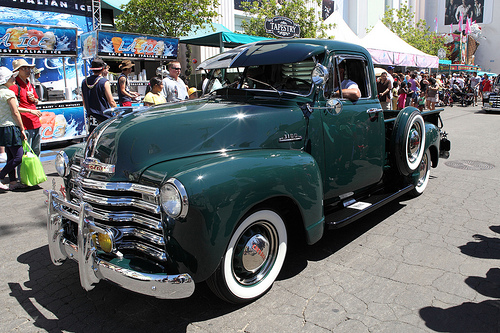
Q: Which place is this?
A: It is a road.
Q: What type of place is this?
A: It is a road.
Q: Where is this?
A: This is at the road.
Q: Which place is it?
A: It is a road.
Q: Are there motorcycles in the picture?
A: No, there are no motorcycles.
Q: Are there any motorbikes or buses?
A: No, there are no motorbikes or buses.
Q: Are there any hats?
A: Yes, there is a hat.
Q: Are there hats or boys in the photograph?
A: Yes, there is a hat.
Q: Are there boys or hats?
A: Yes, there is a hat.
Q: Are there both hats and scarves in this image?
A: No, there is a hat but no scarves.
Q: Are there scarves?
A: No, there are no scarves.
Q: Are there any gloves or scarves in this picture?
A: No, there are no scarves or gloves.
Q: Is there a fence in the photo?
A: No, there are no fences.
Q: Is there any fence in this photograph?
A: No, there are no fences.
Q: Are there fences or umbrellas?
A: No, there are no fences or umbrellas.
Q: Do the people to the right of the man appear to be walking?
A: Yes, the people are walking.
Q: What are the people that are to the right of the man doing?
A: The people are walking.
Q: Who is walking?
A: The people are walking.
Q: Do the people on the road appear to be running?
A: No, the people are walking.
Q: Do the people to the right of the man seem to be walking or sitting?
A: The people are walking.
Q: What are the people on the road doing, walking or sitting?
A: The people are walking.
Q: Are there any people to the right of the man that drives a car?
A: Yes, there are people to the right of the man.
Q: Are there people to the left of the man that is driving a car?
A: No, the people are to the right of the man.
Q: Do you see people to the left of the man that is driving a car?
A: No, the people are to the right of the man.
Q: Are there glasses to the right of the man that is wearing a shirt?
A: No, there are people to the right of the man.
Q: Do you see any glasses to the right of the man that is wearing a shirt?
A: No, there are people to the right of the man.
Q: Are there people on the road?
A: Yes, there are people on the road.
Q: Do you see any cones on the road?
A: No, there are people on the road.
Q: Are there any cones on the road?
A: No, there are people on the road.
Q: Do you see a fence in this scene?
A: No, there are no fences.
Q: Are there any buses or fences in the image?
A: No, there are no fences or buses.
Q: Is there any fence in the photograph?
A: No, there are no fences.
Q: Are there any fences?
A: No, there are no fences.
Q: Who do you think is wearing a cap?
A: The man is wearing a cap.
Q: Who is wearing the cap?
A: The man is wearing a cap.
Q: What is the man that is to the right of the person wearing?
A: The man is wearing a cap.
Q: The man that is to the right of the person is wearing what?
A: The man is wearing a cap.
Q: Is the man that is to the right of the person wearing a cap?
A: Yes, the man is wearing a cap.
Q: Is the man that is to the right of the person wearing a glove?
A: No, the man is wearing a cap.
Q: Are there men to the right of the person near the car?
A: Yes, there is a man to the right of the person.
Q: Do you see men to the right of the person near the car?
A: Yes, there is a man to the right of the person.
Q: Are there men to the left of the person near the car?
A: No, the man is to the right of the person.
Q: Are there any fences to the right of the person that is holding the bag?
A: No, there is a man to the right of the person.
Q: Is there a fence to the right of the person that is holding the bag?
A: No, there is a man to the right of the person.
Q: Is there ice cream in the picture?
A: Yes, there is ice cream.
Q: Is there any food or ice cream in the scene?
A: Yes, there is ice cream.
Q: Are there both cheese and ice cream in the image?
A: No, there is ice cream but no cheese.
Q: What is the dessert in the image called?
A: The dessert is ice cream.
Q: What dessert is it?
A: The dessert is ice cream.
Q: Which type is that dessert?
A: This is ice cream.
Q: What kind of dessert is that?
A: This is ice cream.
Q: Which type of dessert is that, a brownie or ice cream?
A: This is ice cream.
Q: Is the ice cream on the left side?
A: Yes, the ice cream is on the left of the image.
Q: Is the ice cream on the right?
A: No, the ice cream is on the left of the image.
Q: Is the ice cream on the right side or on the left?
A: The ice cream is on the left of the image.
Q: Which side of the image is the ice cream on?
A: The ice cream is on the left of the image.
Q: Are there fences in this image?
A: No, there are no fences.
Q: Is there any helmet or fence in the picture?
A: No, there are no fences or helmets.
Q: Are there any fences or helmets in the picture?
A: No, there are no fences or helmets.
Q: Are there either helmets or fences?
A: No, there are no fences or helmets.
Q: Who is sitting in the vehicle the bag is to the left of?
A: The man is sitting in the car.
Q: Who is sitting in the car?
A: The man is sitting in the car.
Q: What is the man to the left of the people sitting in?
A: The man is sitting in the car.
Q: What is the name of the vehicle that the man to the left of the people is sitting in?
A: The vehicle is a car.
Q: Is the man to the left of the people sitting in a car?
A: Yes, the man is sitting in a car.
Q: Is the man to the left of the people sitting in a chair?
A: No, the man is sitting in a car.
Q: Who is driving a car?
A: The man is driving a car.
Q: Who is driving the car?
A: The man is driving a car.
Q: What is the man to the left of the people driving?
A: The man is driving a car.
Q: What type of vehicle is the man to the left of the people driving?
A: The man is driving a car.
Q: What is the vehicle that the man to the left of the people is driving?
A: The vehicle is a car.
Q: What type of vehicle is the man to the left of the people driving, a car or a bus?
A: The man is driving a car.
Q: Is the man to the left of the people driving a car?
A: Yes, the man is driving a car.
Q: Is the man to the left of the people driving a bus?
A: No, the man is driving a car.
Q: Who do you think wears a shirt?
A: The man wears a shirt.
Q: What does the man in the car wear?
A: The man wears a shirt.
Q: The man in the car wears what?
A: The man wears a shirt.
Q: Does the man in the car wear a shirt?
A: Yes, the man wears a shirt.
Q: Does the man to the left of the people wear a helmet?
A: No, the man wears a shirt.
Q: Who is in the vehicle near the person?
A: The man is in the car.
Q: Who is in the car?
A: The man is in the car.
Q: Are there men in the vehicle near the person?
A: Yes, there is a man in the car.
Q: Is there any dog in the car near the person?
A: No, there is a man in the car.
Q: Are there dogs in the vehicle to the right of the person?
A: No, there is a man in the car.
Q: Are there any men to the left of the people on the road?
A: Yes, there is a man to the left of the people.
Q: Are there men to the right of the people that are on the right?
A: No, the man is to the left of the people.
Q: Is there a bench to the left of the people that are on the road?
A: No, there is a man to the left of the people.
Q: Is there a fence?
A: No, there are no fences.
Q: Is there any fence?
A: No, there are no fences.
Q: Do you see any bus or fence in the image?
A: No, there are no fences or buses.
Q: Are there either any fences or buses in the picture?
A: No, there are no fences or buses.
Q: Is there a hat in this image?
A: Yes, there is a hat.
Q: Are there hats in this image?
A: Yes, there is a hat.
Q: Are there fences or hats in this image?
A: Yes, there is a hat.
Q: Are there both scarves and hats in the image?
A: No, there is a hat but no scarves.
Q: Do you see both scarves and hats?
A: No, there is a hat but no scarves.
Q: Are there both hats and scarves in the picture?
A: No, there is a hat but no scarves.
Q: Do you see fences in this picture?
A: No, there are no fences.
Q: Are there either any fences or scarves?
A: No, there are no fences or scarves.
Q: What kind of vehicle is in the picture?
A: The vehicle is a car.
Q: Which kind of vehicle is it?
A: The vehicle is a car.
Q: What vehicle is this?
A: This is a car.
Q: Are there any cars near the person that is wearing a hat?
A: Yes, there is a car near the person.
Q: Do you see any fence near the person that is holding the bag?
A: No, there is a car near the person.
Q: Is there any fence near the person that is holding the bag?
A: No, there is a car near the person.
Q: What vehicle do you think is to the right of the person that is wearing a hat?
A: The vehicle is a car.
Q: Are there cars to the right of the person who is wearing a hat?
A: Yes, there is a car to the right of the person.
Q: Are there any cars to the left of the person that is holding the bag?
A: No, the car is to the right of the person.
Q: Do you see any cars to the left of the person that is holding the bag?
A: No, the car is to the right of the person.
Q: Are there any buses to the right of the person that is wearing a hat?
A: No, there is a car to the right of the person.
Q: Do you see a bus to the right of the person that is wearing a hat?
A: No, there is a car to the right of the person.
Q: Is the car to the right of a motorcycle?
A: No, the car is to the right of the person.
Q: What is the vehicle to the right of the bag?
A: The vehicle is a car.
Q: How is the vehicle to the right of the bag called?
A: The vehicle is a car.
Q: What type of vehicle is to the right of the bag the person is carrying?
A: The vehicle is a car.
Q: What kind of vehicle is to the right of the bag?
A: The vehicle is a car.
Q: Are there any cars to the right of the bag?
A: Yes, there is a car to the right of the bag.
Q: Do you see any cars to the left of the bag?
A: No, the car is to the right of the bag.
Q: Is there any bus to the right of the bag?
A: No, there is a car to the right of the bag.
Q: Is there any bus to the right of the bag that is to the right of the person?
A: No, there is a car to the right of the bag.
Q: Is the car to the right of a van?
A: No, the car is to the right of the bag.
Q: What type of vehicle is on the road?
A: The vehicle is a car.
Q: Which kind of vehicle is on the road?
A: The vehicle is a car.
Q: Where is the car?
A: The car is on the road.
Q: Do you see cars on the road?
A: Yes, there is a car on the road.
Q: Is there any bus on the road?
A: No, there is a car on the road.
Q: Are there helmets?
A: No, there are no helmets.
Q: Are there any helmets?
A: No, there are no helmets.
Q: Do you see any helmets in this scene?
A: No, there are no helmets.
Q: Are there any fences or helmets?
A: No, there are no helmets or fences.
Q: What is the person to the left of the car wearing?
A: The person is wearing a hat.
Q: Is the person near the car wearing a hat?
A: Yes, the person is wearing a hat.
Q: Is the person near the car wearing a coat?
A: No, the person is wearing a hat.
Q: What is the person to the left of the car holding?
A: The person is holding the bag.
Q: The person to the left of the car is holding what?
A: The person is holding the bag.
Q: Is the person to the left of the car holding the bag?
A: Yes, the person is holding the bag.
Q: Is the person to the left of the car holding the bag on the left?
A: Yes, the person is holding the bag.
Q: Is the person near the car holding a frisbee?
A: No, the person is holding the bag.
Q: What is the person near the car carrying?
A: The person is carrying a bag.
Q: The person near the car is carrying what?
A: The person is carrying a bag.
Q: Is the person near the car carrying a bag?
A: Yes, the person is carrying a bag.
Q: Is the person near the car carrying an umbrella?
A: No, the person is carrying a bag.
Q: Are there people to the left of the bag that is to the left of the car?
A: Yes, there is a person to the left of the bag.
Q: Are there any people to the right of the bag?
A: No, the person is to the left of the bag.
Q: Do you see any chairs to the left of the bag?
A: No, there is a person to the left of the bag.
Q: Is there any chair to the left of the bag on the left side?
A: No, there is a person to the left of the bag.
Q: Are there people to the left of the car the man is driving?
A: Yes, there is a person to the left of the car.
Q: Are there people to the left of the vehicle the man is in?
A: Yes, there is a person to the left of the car.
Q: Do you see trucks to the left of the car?
A: No, there is a person to the left of the car.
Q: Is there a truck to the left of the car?
A: No, there is a person to the left of the car.